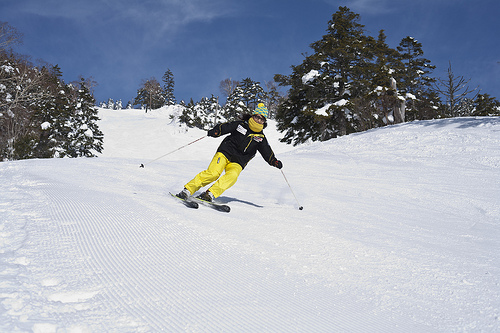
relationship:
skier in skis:
[174, 100, 282, 200] [180, 192, 237, 218]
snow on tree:
[309, 103, 342, 125] [306, 8, 413, 104]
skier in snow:
[174, 100, 282, 200] [309, 103, 342, 125]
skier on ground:
[174, 100, 282, 200] [66, 189, 165, 294]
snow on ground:
[309, 103, 342, 125] [66, 189, 165, 294]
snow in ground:
[309, 103, 342, 125] [66, 189, 165, 294]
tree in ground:
[306, 8, 413, 104] [66, 189, 165, 294]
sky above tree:
[158, 9, 270, 79] [306, 8, 413, 104]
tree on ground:
[306, 8, 413, 104] [66, 189, 165, 294]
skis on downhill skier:
[173, 187, 236, 219] [175, 104, 284, 210]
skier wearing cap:
[174, 100, 282, 200] [248, 97, 269, 127]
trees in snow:
[0, 29, 499, 173] [3, 88, 496, 330]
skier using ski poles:
[167, 92, 293, 214] [140, 133, 295, 190]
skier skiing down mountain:
[174, 100, 282, 200] [4, 112, 498, 318]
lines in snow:
[184, 255, 244, 329] [3, 88, 496, 330]